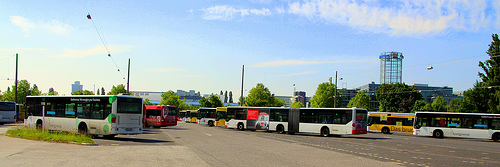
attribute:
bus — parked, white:
[24, 92, 147, 140]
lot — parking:
[2, 118, 499, 166]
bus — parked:
[267, 102, 368, 137]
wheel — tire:
[320, 125, 331, 137]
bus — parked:
[414, 107, 499, 141]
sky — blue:
[2, 1, 499, 95]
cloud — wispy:
[200, 0, 493, 37]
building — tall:
[376, 55, 406, 86]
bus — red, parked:
[145, 103, 180, 131]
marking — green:
[101, 123, 111, 136]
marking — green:
[108, 92, 117, 104]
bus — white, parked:
[225, 103, 289, 135]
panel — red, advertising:
[245, 108, 261, 121]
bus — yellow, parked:
[367, 109, 416, 135]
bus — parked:
[214, 104, 227, 127]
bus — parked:
[197, 104, 217, 128]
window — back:
[117, 95, 146, 115]